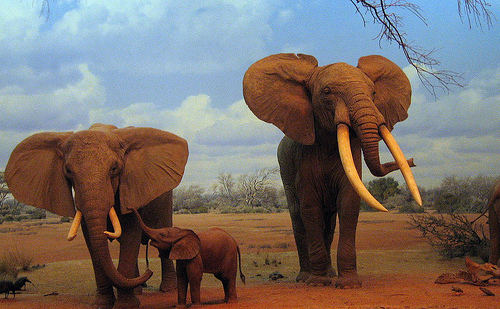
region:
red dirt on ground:
[1, 211, 498, 306]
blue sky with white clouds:
[0, 1, 498, 196]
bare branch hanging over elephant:
[350, 0, 499, 100]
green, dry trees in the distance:
[1, 171, 498, 216]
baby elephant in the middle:
[128, 207, 245, 307]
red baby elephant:
[126, 207, 246, 307]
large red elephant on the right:
[242, 52, 423, 284]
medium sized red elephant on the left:
[5, 123, 189, 306]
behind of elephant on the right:
[471, 179, 498, 264]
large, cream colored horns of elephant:
[336, 125, 424, 209]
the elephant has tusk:
[159, 58, 498, 261]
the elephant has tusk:
[228, 37, 388, 231]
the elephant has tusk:
[261, 41, 421, 302]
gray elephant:
[240, 53, 426, 280]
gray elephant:
[153, 225, 237, 289]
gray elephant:
[19, 130, 138, 282]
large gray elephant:
[248, 48, 423, 273]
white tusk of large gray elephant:
[332, 126, 382, 232]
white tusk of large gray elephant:
[379, 121, 430, 202]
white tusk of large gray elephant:
[67, 212, 88, 239]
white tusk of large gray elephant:
[103, 202, 128, 239]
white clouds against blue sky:
[7, 10, 227, 122]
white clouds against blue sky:
[424, 98, 490, 160]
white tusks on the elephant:
[288, 146, 431, 246]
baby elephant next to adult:
[146, 198, 251, 293]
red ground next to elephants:
[263, 276, 295, 307]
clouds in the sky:
[177, 73, 237, 120]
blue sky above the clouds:
[304, 21, 350, 44]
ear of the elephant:
[224, 42, 321, 152]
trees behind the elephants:
[206, 158, 259, 210]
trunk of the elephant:
[349, 109, 389, 182]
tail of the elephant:
[454, 175, 499, 239]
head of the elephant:
[49, 98, 164, 213]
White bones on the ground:
[430, 251, 499, 294]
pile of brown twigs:
[410, 201, 493, 261]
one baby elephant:
[135, 206, 252, 307]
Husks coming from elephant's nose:
[333, 112, 423, 211]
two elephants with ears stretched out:
[7, 44, 420, 218]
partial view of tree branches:
[348, 0, 498, 102]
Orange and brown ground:
[4, 216, 496, 307]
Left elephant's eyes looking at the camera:
[57, 146, 137, 193]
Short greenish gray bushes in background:
[3, 164, 492, 211]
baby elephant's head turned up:
[120, 204, 204, 267]